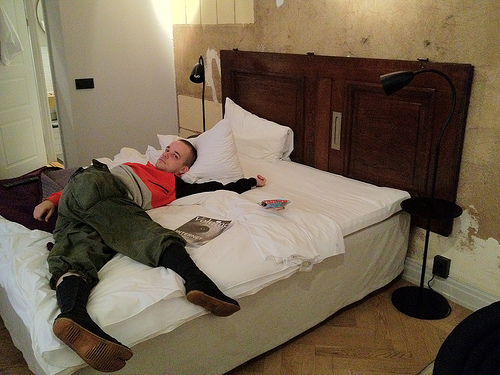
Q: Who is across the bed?
A: Man draped across bed.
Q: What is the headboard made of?
A: Wood.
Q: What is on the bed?
A: A man sprawled out.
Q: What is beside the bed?
A: A small black table.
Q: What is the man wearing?
A: A pair of green pants.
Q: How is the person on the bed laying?
A: Twisted up.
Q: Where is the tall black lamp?
A: By the bed.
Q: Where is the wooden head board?
A: Behind the mattress.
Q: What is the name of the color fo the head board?
A: Brown.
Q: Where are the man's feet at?
A: Hanging off the bedside.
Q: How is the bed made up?
A: It is not.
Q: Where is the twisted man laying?
A: On the bed.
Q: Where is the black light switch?
A: By the door.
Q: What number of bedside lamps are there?
A: Two.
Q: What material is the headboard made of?
A: Wood.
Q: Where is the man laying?
A: On the bed.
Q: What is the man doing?
A: Laying down.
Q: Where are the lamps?
A: Beside the bed.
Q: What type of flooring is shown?
A: Wood flooring.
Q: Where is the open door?
A: Behind the man.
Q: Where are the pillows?
A: On the bed.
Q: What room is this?
A: A bedroom.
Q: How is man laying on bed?
A: Spread out.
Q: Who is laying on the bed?
A: A man.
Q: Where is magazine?
A: In foreground.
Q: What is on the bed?
A: A magazine.